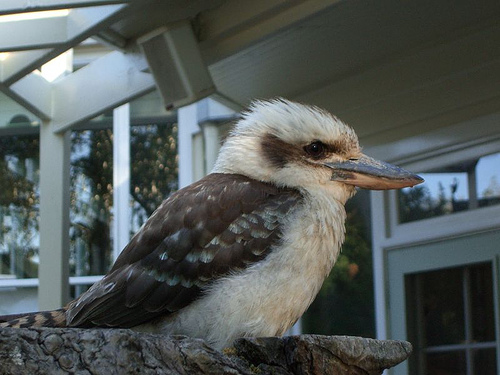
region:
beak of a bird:
[328, 149, 429, 193]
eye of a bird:
[300, 135, 331, 163]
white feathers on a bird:
[197, 245, 214, 265]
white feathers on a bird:
[183, 246, 199, 266]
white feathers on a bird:
[155, 245, 172, 262]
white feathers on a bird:
[192, 215, 205, 231]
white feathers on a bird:
[162, 268, 179, 289]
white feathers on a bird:
[202, 187, 220, 203]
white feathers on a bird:
[177, 273, 199, 292]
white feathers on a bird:
[97, 275, 118, 294]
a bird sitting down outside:
[11, 100, 428, 340]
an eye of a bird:
[305, 135, 325, 155]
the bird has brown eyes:
[300, 135, 325, 155]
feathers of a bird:
[45, 180, 300, 350]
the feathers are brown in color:
[75, 175, 290, 325]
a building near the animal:
[15, 0, 481, 370]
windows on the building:
[1, 36, 495, 362]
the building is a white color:
[8, 5, 482, 372]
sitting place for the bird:
[14, 327, 429, 372]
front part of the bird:
[196, 177, 356, 352]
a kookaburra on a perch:
[5, 87, 430, 372]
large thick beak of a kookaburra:
[326, 148, 426, 197]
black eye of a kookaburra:
[297, 135, 334, 160]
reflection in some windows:
[380, 135, 499, 224]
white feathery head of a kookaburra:
[211, 89, 428, 214]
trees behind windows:
[5, 110, 178, 280]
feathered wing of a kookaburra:
[65, 167, 305, 332]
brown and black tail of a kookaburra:
[2, 298, 72, 328]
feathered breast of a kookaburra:
[307, 195, 348, 303]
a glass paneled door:
[383, 229, 498, 373]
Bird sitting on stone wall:
[13, 101, 423, 326]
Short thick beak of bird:
[338, 151, 425, 190]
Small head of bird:
[223, 95, 426, 194]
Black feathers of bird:
[61, 170, 287, 327]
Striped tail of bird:
[1, 306, 63, 327]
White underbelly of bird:
[183, 186, 350, 349]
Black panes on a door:
[411, 260, 498, 373]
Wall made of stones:
[10, 323, 410, 373]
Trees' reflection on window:
[1, 124, 172, 279]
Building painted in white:
[0, 6, 498, 330]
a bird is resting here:
[6, 93, 431, 358]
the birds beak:
[341, 135, 423, 202]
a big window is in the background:
[299, 127, 496, 374]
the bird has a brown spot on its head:
[255, 113, 305, 174]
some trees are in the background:
[6, 128, 183, 245]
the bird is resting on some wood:
[14, 321, 404, 372]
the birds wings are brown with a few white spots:
[71, 174, 263, 321]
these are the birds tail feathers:
[2, 278, 71, 348]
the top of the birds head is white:
[253, 93, 343, 138]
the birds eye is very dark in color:
[298, 128, 337, 165]